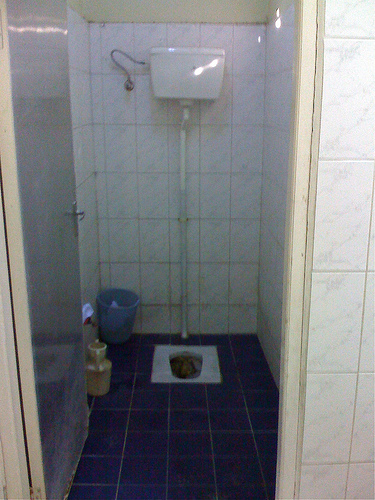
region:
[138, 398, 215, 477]
the ground is tile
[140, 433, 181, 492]
the ground is blue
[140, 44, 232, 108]
the tank is white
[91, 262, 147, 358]
the basket is blue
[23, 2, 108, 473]
the door is white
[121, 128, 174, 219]
the wall is tiled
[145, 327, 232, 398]
there's a hole in the ground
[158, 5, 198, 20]
the ceiling is white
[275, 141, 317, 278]
the edge of the door is white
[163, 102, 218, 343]
the pipe is white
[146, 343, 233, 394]
hole in floor where toilet should be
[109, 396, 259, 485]
blue tile of a bathroom floor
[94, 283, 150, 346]
light blue trash basket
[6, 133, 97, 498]
opened door of a bathroom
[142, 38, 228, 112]
white toilet tank on a wall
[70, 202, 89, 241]
silver door handle on bathroom door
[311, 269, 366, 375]
cream, rectangular tile on bathroom wall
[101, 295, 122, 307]
garbage in trash basket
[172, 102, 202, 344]
pipe of toilet tank on wall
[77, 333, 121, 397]
cream colored urn jug on bathroom floor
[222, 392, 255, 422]
part of a toilet floor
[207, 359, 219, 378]
edge of a toilet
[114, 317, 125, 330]
part of a litter bin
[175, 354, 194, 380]
part of some wastes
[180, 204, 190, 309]
part of a white post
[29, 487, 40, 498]
hinge of a door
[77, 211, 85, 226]
handle of a door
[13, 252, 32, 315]
edge of a door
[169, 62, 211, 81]
tank of a toilet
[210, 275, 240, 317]
part of the toilet wall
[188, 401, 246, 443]
part of a toilet floor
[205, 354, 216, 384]
edge of a toilet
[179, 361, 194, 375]
part of a some wastes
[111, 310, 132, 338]
part of a litter bin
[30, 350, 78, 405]
surface of a door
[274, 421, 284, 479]
edge of a door boundary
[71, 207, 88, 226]
part of a door handle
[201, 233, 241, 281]
part of the toilet wall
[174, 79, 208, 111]
part of a toilet tank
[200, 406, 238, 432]
part of a toilet floor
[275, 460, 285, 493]
part of a door boundary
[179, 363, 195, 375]
part of some wastes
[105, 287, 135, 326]
part of a litter bin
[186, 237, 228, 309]
part of a toilet wall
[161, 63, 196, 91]
part of a toilet tank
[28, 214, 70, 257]
surface of a door